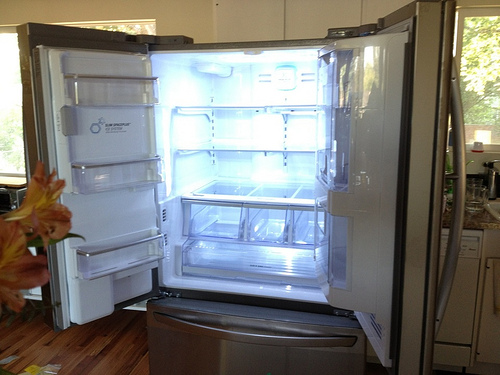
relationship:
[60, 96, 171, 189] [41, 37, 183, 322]
ice maker inside of door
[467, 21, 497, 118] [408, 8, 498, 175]
trees outside of window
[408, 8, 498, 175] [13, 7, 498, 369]
window inside kitchen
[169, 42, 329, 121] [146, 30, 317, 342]
shefl inside refrigerator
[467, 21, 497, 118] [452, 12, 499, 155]
trees outside window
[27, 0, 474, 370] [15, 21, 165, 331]
freezer refrigirator has door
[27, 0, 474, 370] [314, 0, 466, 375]
freezer refrigirator has door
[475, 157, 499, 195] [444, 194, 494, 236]
cannister on countertop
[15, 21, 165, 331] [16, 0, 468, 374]
door of fridge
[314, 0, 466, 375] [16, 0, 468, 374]
door of fridge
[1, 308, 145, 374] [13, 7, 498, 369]
floor in kitchen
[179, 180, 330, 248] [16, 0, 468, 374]
boxes in fridge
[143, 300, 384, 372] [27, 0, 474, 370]
freezer refrigerator on bottom of freezer refrigirator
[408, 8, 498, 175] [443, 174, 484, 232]
window above counter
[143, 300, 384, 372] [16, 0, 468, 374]
freezer refrigerator of fridge